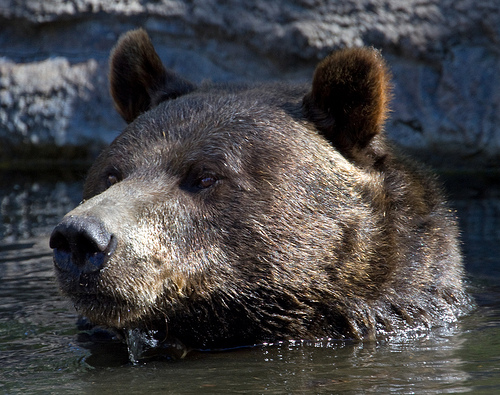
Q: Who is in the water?
A: Bear.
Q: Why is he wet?
A: He is in the water.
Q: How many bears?
A: One.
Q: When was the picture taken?
A: Daytime.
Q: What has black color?
A: Nose.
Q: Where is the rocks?
A: Behind the bear.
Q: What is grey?
A: Rocks.